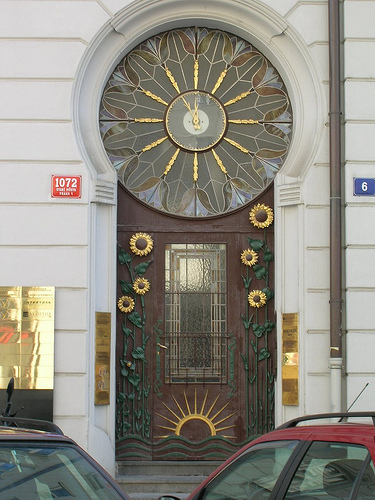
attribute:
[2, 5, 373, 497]
building — white, large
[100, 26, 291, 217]
clock — golden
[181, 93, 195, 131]
clock hand — gold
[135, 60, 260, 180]
sun — gold, yellow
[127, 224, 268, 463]
door — brown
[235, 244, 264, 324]
flowers — yellow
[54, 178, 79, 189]
numbers — white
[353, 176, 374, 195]
sign — blue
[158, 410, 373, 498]
car — red, parked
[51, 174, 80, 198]
sign — red, rectangular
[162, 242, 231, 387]
glass — decorative, stained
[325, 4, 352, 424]
pipe — long, tall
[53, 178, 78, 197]
print — white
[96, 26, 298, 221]
window — large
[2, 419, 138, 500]
car — parked